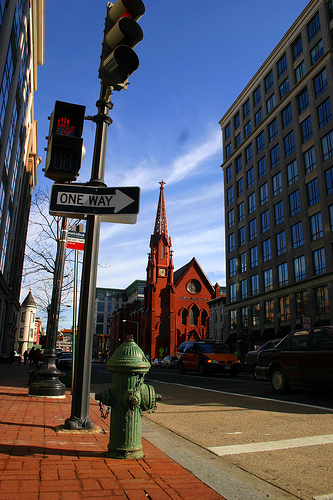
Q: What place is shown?
A: It is a city.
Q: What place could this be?
A: It is a city.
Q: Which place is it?
A: It is a city.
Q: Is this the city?
A: Yes, it is the city.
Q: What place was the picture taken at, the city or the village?
A: It was taken at the city.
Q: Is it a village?
A: No, it is a city.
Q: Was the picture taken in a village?
A: No, the picture was taken in a city.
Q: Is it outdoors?
A: Yes, it is outdoors.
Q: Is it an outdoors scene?
A: Yes, it is outdoors.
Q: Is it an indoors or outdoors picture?
A: It is outdoors.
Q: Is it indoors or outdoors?
A: It is outdoors.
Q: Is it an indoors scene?
A: No, it is outdoors.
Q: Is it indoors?
A: No, it is outdoors.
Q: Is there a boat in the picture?
A: No, there are no boats.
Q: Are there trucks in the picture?
A: No, there are no trucks.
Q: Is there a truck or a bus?
A: No, there are no trucks or buses.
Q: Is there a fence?
A: No, there are no fences.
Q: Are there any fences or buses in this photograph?
A: No, there are no fences or buses.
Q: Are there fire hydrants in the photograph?
A: Yes, there is a fire hydrant.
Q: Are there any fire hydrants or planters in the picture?
A: Yes, there is a fire hydrant.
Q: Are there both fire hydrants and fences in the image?
A: No, there is a fire hydrant but no fences.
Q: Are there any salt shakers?
A: No, there are no salt shakers.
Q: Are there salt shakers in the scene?
A: No, there are no salt shakers.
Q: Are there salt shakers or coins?
A: No, there are no salt shakers or coins.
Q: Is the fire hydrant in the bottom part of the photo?
A: Yes, the fire hydrant is in the bottom of the image.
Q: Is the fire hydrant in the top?
A: No, the fire hydrant is in the bottom of the image.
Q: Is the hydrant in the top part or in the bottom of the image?
A: The hydrant is in the bottom of the image.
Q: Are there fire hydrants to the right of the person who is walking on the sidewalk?
A: Yes, there is a fire hydrant to the right of the person.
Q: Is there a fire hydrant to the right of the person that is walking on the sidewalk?
A: Yes, there is a fire hydrant to the right of the person.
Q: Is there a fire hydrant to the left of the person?
A: No, the fire hydrant is to the right of the person.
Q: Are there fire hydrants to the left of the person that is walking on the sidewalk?
A: No, the fire hydrant is to the right of the person.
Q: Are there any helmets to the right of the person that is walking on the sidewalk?
A: No, there is a fire hydrant to the right of the person.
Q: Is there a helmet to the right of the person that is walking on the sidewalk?
A: No, there is a fire hydrant to the right of the person.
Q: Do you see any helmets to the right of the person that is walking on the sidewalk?
A: No, there is a fire hydrant to the right of the person.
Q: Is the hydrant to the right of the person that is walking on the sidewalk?
A: Yes, the hydrant is to the right of the person.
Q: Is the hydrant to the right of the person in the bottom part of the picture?
A: Yes, the hydrant is to the right of the person.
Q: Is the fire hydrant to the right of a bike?
A: No, the fire hydrant is to the right of the person.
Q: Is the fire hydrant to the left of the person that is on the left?
A: No, the fire hydrant is to the right of the person.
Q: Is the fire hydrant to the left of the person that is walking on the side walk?
A: No, the fire hydrant is to the right of the person.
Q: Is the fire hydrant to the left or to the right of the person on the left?
A: The fire hydrant is to the right of the person.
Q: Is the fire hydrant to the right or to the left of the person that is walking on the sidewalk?
A: The fire hydrant is to the right of the person.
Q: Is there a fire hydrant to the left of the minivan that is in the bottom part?
A: Yes, there is a fire hydrant to the left of the minivan.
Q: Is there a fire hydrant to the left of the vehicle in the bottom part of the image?
A: Yes, there is a fire hydrant to the left of the minivan.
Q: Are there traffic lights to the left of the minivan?
A: No, there is a fire hydrant to the left of the minivan.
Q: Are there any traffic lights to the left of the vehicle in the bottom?
A: No, there is a fire hydrant to the left of the minivan.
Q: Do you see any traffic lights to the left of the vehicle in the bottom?
A: No, there is a fire hydrant to the left of the minivan.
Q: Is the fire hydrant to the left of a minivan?
A: Yes, the fire hydrant is to the left of a minivan.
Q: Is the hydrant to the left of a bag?
A: No, the hydrant is to the left of a minivan.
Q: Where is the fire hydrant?
A: The fire hydrant is on the sidewalk.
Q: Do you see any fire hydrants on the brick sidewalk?
A: Yes, there is a fire hydrant on the sidewalk.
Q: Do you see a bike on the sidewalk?
A: No, there is a fire hydrant on the sidewalk.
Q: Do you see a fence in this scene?
A: No, there are no fences.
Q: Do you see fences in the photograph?
A: No, there are no fences.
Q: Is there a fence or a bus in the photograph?
A: No, there are no fences or buses.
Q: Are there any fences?
A: No, there are no fences.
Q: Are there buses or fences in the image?
A: No, there are no fences or buses.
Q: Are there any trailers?
A: No, there are no trailers.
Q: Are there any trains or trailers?
A: No, there are no trailers or trains.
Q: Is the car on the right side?
A: Yes, the car is on the right of the image.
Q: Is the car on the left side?
A: No, the car is on the right of the image.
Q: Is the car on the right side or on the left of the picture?
A: The car is on the right of the image.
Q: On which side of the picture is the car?
A: The car is on the right of the image.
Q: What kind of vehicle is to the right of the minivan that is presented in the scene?
A: The vehicle is a car.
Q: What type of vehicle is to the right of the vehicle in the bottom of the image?
A: The vehicle is a car.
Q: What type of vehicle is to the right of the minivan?
A: The vehicle is a car.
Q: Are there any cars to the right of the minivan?
A: Yes, there is a car to the right of the minivan.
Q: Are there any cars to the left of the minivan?
A: No, the car is to the right of the minivan.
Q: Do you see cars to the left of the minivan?
A: No, the car is to the right of the minivan.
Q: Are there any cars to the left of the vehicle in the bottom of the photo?
A: No, the car is to the right of the minivan.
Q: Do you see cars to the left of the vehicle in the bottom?
A: No, the car is to the right of the minivan.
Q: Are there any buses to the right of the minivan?
A: No, there is a car to the right of the minivan.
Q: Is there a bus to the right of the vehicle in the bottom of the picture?
A: No, there is a car to the right of the minivan.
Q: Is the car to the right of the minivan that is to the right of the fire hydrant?
A: Yes, the car is to the right of the minivan.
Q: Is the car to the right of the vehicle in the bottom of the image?
A: Yes, the car is to the right of the minivan.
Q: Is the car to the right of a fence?
A: No, the car is to the right of the minivan.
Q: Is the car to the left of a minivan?
A: No, the car is to the right of a minivan.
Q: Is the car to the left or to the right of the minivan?
A: The car is to the right of the minivan.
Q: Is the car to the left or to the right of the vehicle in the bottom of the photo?
A: The car is to the right of the minivan.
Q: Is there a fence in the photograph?
A: No, there are no fences.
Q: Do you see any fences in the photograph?
A: No, there are no fences.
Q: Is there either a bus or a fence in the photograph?
A: No, there are no fences or buses.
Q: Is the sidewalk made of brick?
A: Yes, the sidewalk is made of brick.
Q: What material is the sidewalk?
A: The sidewalk is made of brick.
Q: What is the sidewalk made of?
A: The sidewalk is made of brick.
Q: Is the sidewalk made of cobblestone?
A: No, the sidewalk is made of brick.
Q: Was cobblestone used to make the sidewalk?
A: No, the sidewalk is made of brick.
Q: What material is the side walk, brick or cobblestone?
A: The side walk is made of brick.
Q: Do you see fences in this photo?
A: No, there are no fences.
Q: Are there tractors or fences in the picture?
A: No, there are no fences or tractors.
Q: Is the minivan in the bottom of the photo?
A: Yes, the minivan is in the bottom of the image.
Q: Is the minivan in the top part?
A: No, the minivan is in the bottom of the image.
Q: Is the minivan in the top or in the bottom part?
A: The minivan is in the bottom of the image.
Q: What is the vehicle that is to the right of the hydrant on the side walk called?
A: The vehicle is a minivan.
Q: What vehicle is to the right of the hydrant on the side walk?
A: The vehicle is a minivan.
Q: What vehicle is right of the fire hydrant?
A: The vehicle is a minivan.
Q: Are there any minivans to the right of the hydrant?
A: Yes, there is a minivan to the right of the hydrant.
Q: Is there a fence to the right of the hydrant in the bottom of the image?
A: No, there is a minivan to the right of the fire hydrant.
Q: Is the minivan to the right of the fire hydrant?
A: Yes, the minivan is to the right of the fire hydrant.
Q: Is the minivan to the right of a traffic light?
A: No, the minivan is to the right of the fire hydrant.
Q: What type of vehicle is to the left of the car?
A: The vehicle is a minivan.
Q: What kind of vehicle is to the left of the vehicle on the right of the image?
A: The vehicle is a minivan.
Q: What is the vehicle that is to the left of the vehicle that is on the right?
A: The vehicle is a minivan.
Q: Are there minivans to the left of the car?
A: Yes, there is a minivan to the left of the car.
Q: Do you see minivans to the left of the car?
A: Yes, there is a minivan to the left of the car.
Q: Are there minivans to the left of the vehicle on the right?
A: Yes, there is a minivan to the left of the car.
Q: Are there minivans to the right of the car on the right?
A: No, the minivan is to the left of the car.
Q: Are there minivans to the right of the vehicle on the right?
A: No, the minivan is to the left of the car.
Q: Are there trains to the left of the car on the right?
A: No, there is a minivan to the left of the car.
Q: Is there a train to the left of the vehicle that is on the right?
A: No, there is a minivan to the left of the car.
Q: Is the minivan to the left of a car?
A: Yes, the minivan is to the left of a car.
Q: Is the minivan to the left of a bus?
A: No, the minivan is to the left of a car.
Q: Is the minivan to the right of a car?
A: No, the minivan is to the left of a car.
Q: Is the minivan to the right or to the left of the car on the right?
A: The minivan is to the left of the car.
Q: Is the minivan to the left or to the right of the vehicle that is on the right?
A: The minivan is to the left of the car.